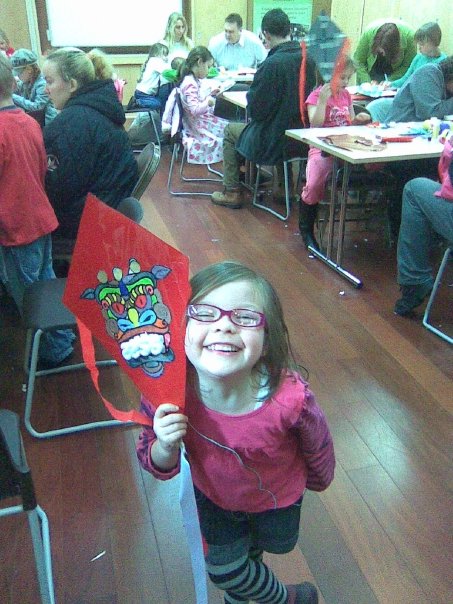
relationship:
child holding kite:
[134, 258, 337, 602] [69, 188, 186, 406]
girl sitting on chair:
[174, 54, 242, 162] [144, 87, 235, 197]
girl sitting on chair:
[322, 157, 404, 253] [306, 54, 363, 236]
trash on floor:
[79, 540, 110, 572] [9, 164, 450, 596]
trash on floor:
[88, 542, 110, 566] [10, 205, 451, 597]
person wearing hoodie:
[38, 45, 141, 284] [29, 86, 133, 243]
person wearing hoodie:
[38, 45, 141, 284] [34, 77, 134, 224]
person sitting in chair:
[38, 45, 141, 284] [38, 119, 173, 285]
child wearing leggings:
[134, 258, 337, 602] [190, 554, 308, 602]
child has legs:
[134, 258, 337, 602] [187, 493, 317, 601]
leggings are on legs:
[190, 554, 308, 602] [187, 493, 317, 601]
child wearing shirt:
[134, 258, 337, 602] [127, 362, 343, 524]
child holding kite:
[134, 258, 337, 602] [35, 187, 212, 432]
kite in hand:
[35, 187, 212, 432] [144, 386, 190, 457]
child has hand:
[134, 258, 337, 602] [144, 386, 190, 457]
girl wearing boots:
[297, 54, 363, 260] [279, 194, 332, 250]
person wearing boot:
[206, 9, 308, 213] [201, 177, 263, 214]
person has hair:
[38, 45, 141, 284] [28, 26, 121, 95]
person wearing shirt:
[342, 9, 434, 101] [344, 3, 430, 87]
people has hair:
[161, 7, 199, 79] [154, 0, 203, 117]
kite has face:
[59, 190, 189, 424] [55, 251, 199, 399]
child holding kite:
[97, 227, 345, 602] [38, 175, 204, 436]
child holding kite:
[134, 258, 337, 602] [43, 171, 201, 465]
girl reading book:
[173, 40, 234, 169] [203, 62, 252, 103]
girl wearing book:
[173, 40, 234, 169] [203, 62, 252, 103]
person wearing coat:
[38, 45, 141, 284] [36, 77, 146, 256]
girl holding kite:
[297, 54, 363, 260] [314, 27, 354, 112]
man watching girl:
[214, 6, 265, 90] [121, 36, 181, 104]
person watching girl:
[38, 45, 141, 284] [121, 36, 181, 104]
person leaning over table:
[349, 17, 422, 91] [201, 82, 451, 118]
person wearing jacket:
[349, 17, 422, 91] [351, 9, 433, 97]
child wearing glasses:
[134, 258, 337, 602] [176, 287, 282, 335]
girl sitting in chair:
[173, 40, 234, 169] [161, 88, 248, 201]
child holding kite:
[134, 258, 337, 602] [57, 189, 194, 418]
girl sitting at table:
[173, 40, 234, 169] [200, 67, 273, 109]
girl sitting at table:
[130, 40, 178, 111] [200, 67, 273, 109]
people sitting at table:
[161, 10, 195, 54] [200, 67, 273, 109]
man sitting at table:
[208, 9, 269, 73] [200, 67, 273, 109]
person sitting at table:
[206, 9, 308, 213] [200, 67, 273, 109]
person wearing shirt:
[1, 43, 81, 369] [2, 104, 60, 251]